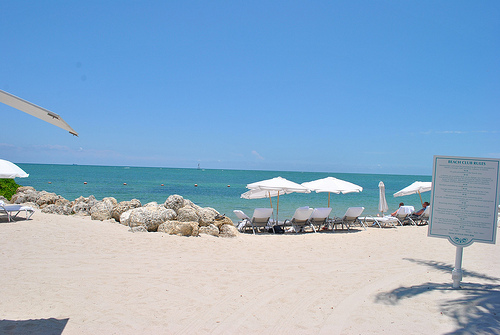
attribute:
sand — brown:
[3, 200, 496, 334]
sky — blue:
[0, 1, 496, 176]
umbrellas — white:
[237, 165, 437, 211]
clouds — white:
[125, 42, 165, 72]